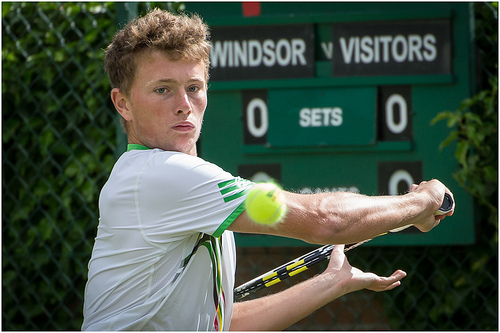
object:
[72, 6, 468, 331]
tennis game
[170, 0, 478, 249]
scoreboard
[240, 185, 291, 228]
tennis ball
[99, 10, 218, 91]
hair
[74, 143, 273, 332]
shirt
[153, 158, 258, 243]
sleeve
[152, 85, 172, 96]
eyes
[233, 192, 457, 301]
tennis racquet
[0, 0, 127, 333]
fence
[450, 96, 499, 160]
greenery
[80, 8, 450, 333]
man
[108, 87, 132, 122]
right ear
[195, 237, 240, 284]
stripes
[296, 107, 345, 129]
set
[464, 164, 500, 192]
leaves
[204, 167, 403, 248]
arm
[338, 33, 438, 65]
visitors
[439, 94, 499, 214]
tree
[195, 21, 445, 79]
sign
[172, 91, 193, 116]
nose